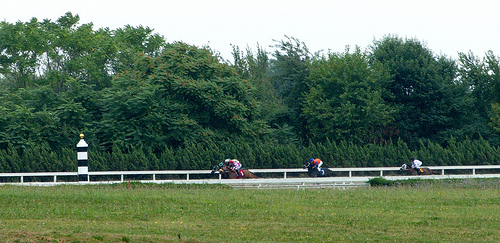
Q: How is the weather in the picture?
A: It is cloudy.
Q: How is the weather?
A: It is cloudy.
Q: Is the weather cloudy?
A: Yes, it is cloudy.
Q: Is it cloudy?
A: Yes, it is cloudy.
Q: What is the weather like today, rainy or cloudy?
A: It is cloudy.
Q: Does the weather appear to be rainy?
A: No, it is cloudy.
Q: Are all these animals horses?
A: Yes, all the animals are horses.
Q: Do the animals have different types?
A: No, all the animals are horses.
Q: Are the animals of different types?
A: No, all the animals are horses.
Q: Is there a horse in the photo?
A: Yes, there is a horse.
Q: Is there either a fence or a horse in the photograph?
A: Yes, there is a horse.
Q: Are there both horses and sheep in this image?
A: No, there is a horse but no sheep.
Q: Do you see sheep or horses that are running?
A: Yes, the horse is running.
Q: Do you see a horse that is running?
A: Yes, there is a horse that is running.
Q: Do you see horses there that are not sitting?
A: Yes, there is a horse that is running .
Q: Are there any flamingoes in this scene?
A: No, there are no flamingoes.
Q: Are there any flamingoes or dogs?
A: No, there are no flamingoes or dogs.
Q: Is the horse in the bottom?
A: Yes, the horse is in the bottom of the image.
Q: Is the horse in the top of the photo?
A: No, the horse is in the bottom of the image.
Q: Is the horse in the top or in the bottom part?
A: The horse is in the bottom of the image.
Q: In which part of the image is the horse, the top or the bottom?
A: The horse is in the bottom of the image.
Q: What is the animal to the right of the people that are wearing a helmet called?
A: The animal is a horse.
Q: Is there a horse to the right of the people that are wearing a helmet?
A: Yes, there is a horse to the right of the people.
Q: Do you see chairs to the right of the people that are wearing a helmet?
A: No, there is a horse to the right of the people.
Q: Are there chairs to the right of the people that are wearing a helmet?
A: No, there is a horse to the right of the people.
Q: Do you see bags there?
A: No, there are no bags.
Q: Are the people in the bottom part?
A: Yes, the people are in the bottom of the image.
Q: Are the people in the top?
A: No, the people are in the bottom of the image.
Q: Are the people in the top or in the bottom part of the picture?
A: The people are in the bottom of the image.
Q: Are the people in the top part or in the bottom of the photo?
A: The people are in the bottom of the image.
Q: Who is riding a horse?
A: The people are riding a horse.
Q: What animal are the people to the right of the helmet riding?
A: The people are riding a horse.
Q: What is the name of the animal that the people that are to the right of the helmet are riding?
A: The animal is a horse.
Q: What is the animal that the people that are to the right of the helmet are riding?
A: The animal is a horse.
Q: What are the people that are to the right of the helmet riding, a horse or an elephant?
A: The people are riding a horse.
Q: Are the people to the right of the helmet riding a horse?
A: Yes, the people are riding a horse.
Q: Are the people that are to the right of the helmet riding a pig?
A: No, the people are riding a horse.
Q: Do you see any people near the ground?
A: Yes, there are people near the ground.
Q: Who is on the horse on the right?
A: The people are on the horse.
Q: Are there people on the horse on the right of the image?
A: Yes, there are people on the horse.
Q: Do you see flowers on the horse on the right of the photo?
A: No, there are people on the horse.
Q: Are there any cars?
A: No, there are no cars.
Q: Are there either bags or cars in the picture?
A: No, there are no cars or bags.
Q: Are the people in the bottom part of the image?
A: Yes, the people are in the bottom of the image.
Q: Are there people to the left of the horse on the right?
A: Yes, there are people to the left of the horse.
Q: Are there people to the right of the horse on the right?
A: No, the people are to the left of the horse.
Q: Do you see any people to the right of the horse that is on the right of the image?
A: No, the people are to the left of the horse.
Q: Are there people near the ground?
A: Yes, there are people near the ground.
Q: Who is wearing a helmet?
A: The people are wearing a helmet.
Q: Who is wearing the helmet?
A: The people are wearing a helmet.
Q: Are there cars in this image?
A: No, there are no cars.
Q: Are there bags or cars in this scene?
A: No, there are no cars or bags.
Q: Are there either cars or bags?
A: No, there are no cars or bags.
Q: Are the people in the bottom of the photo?
A: Yes, the people are in the bottom of the image.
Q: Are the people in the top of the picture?
A: No, the people are in the bottom of the image.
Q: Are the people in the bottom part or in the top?
A: The people are in the bottom of the image.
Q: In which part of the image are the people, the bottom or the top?
A: The people are in the bottom of the image.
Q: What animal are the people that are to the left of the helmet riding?
A: The people are riding a horse.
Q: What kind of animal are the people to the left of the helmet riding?
A: The people are riding a horse.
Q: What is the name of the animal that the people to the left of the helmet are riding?
A: The animal is a horse.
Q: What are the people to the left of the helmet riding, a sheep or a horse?
A: The people are riding a horse.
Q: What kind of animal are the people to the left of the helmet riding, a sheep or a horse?
A: The people are riding a horse.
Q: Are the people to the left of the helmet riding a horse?
A: Yes, the people are riding a horse.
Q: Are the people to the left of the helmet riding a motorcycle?
A: No, the people are riding a horse.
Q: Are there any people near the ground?
A: Yes, there are people near the ground.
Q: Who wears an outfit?
A: The people wear an outfit.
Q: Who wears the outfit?
A: The people wear an outfit.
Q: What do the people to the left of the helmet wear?
A: The people wear an outfit.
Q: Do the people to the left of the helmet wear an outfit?
A: Yes, the people wear an outfit.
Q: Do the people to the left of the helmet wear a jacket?
A: No, the people wear an outfit.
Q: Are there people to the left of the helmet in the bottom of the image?
A: Yes, there are people to the left of the helmet.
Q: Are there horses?
A: Yes, there is a horse.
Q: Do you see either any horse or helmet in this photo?
A: Yes, there is a horse.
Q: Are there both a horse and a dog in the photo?
A: No, there is a horse but no dogs.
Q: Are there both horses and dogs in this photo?
A: No, there is a horse but no dogs.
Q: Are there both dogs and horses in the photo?
A: No, there is a horse but no dogs.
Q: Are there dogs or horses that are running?
A: Yes, the horse is running.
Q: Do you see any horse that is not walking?
A: Yes, there is a horse that is running .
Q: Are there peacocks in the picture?
A: No, there are no peacocks.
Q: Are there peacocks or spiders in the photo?
A: No, there are no peacocks or spiders.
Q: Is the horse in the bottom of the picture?
A: Yes, the horse is in the bottom of the image.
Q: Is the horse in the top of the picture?
A: No, the horse is in the bottom of the image.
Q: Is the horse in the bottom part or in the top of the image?
A: The horse is in the bottom of the image.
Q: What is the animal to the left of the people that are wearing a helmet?
A: The animal is a horse.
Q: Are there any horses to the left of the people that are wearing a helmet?
A: Yes, there is a horse to the left of the people.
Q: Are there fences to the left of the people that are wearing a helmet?
A: No, there is a horse to the left of the people.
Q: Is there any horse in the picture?
A: Yes, there is a horse.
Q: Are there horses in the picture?
A: Yes, there is a horse.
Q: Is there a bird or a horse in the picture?
A: Yes, there is a horse.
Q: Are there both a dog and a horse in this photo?
A: No, there is a horse but no dogs.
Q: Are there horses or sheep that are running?
A: Yes, the horse is running.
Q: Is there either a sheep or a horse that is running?
A: Yes, the horse is running.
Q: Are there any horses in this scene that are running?
A: Yes, there is a horse that is running.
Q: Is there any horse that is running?
A: Yes, there is a horse that is running.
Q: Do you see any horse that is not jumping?
A: Yes, there is a horse that is running .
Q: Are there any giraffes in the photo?
A: No, there are no giraffes.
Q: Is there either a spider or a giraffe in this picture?
A: No, there are no giraffes or spiders.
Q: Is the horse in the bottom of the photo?
A: Yes, the horse is in the bottom of the image.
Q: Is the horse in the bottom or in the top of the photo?
A: The horse is in the bottom of the image.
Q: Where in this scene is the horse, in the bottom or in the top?
A: The horse is in the bottom of the image.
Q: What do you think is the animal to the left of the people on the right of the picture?
A: The animal is a horse.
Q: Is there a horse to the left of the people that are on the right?
A: Yes, there is a horse to the left of the people.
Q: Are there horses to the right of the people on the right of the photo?
A: No, the horse is to the left of the people.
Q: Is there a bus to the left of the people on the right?
A: No, there is a horse to the left of the people.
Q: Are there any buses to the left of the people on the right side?
A: No, there is a horse to the left of the people.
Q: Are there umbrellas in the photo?
A: No, there are no umbrellas.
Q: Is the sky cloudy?
A: Yes, the sky is cloudy.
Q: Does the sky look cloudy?
A: Yes, the sky is cloudy.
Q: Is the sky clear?
A: No, the sky is cloudy.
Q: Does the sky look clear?
A: No, the sky is cloudy.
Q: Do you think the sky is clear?
A: No, the sky is cloudy.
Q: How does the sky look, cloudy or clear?
A: The sky is cloudy.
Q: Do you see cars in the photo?
A: No, there are no cars.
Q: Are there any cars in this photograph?
A: No, there are no cars.